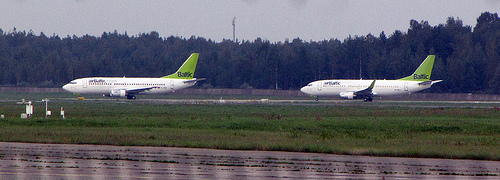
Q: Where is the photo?
A: Runway.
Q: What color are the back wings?
A: Green.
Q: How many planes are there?
A: Two.